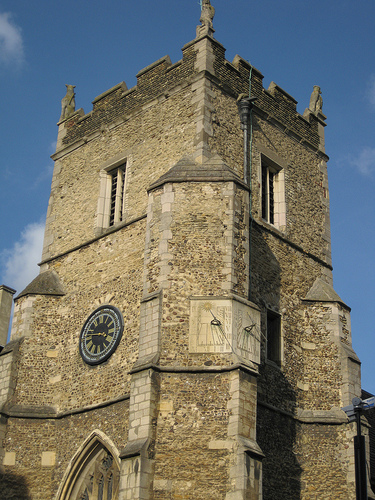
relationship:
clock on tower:
[78, 306, 126, 365] [7, 0, 353, 492]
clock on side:
[78, 306, 126, 365] [28, 72, 190, 499]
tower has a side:
[7, 0, 353, 492] [28, 72, 190, 499]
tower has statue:
[7, 0, 353, 492] [309, 84, 324, 114]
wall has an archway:
[4, 413, 148, 499] [56, 428, 127, 500]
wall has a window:
[28, 72, 190, 499] [95, 159, 132, 238]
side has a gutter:
[201, 52, 351, 436] [231, 60, 260, 197]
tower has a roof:
[7, 0, 353, 492] [7, 268, 75, 310]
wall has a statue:
[4, 413, 148, 499] [51, 79, 82, 129]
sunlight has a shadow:
[2, 0, 362, 111] [259, 363, 307, 496]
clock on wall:
[78, 306, 126, 365] [4, 413, 148, 499]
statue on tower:
[51, 79, 82, 129] [7, 0, 353, 492]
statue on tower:
[192, 0, 223, 42] [7, 0, 353, 492]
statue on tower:
[306, 79, 329, 126] [7, 0, 353, 492]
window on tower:
[95, 159, 132, 238] [7, 0, 353, 492]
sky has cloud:
[2, 1, 373, 264] [2, 8, 30, 76]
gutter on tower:
[231, 60, 260, 197] [7, 0, 353, 492]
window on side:
[56, 428, 127, 500] [28, 72, 190, 499]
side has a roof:
[28, 72, 190, 499] [7, 268, 75, 310]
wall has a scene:
[146, 159, 374, 499] [194, 285, 261, 360]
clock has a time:
[78, 306, 126, 365] [82, 331, 114, 342]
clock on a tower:
[78, 306, 126, 365] [7, 0, 353, 492]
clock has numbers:
[78, 306, 126, 365] [96, 315, 114, 324]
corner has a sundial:
[144, 168, 255, 499] [194, 285, 261, 360]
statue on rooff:
[51, 79, 82, 129] [62, 43, 334, 157]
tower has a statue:
[7, 0, 353, 492] [309, 84, 324, 114]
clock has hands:
[78, 306, 126, 365] [82, 331, 114, 342]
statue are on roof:
[309, 84, 324, 114] [7, 268, 75, 310]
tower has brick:
[7, 0, 353, 492] [133, 100, 201, 131]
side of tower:
[28, 72, 190, 499] [7, 0, 353, 492]